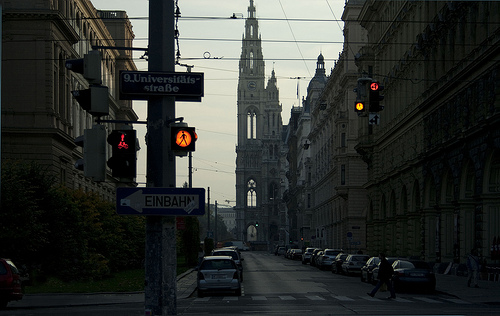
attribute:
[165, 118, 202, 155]
walking light — lit up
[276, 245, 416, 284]
cars — parked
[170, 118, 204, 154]
light — orange 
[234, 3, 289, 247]
building — tall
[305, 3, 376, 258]
building — cream colored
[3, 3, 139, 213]
building — large, light colored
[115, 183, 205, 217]
sign — black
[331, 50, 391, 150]
light — red 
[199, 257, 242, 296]
car — light colored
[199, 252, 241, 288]
car — silver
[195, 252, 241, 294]
vehicle — not moving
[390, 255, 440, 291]
vehicle — not moving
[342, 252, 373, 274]
vehicle — not moving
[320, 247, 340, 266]
vehicle — not moving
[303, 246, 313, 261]
vehicle — not moving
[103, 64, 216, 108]
sign — black